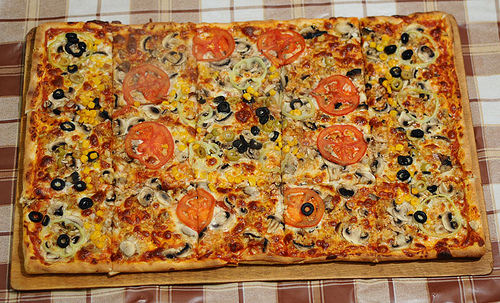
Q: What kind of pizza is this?
A: Vegetable pizza.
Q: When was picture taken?
A: At lunch time.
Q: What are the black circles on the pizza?
A: Olive.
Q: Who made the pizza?
A: A cook.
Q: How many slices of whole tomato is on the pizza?
A: 8.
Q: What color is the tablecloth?
A: Picnic red and white.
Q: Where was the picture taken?
A: In a kitchen.